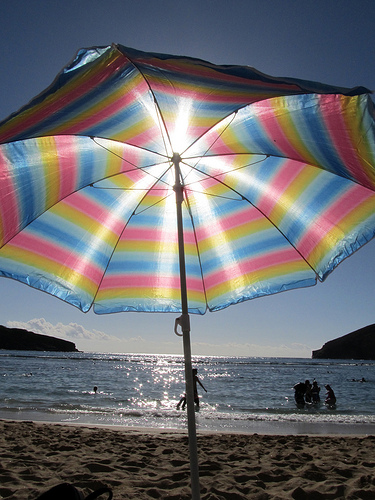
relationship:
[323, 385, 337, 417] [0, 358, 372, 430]
people in water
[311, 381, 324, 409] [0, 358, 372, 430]
people in water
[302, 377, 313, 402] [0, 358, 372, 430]
people in water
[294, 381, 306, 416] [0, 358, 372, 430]
people in water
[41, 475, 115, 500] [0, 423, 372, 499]
bag in sand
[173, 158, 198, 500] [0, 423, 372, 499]
pole in sand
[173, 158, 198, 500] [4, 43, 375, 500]
pole from umbrella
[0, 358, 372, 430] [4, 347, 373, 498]
water in a bay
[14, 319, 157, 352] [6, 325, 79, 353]
clouds are over hill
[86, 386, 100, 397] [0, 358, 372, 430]
head in water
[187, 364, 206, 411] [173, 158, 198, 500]
man behind pole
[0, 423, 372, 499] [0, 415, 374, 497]
sand has track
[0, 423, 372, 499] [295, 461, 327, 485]
sand has track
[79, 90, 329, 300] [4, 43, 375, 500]
sun through umbrella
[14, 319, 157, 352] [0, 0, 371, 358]
clouds are in sky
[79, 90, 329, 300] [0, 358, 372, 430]
sun reflecting on water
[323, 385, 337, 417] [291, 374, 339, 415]
people in group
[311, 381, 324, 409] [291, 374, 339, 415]
people in group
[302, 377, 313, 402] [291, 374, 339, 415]
people in group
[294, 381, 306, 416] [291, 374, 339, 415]
people in group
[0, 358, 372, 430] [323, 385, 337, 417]
water has people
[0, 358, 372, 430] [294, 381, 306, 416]
water has people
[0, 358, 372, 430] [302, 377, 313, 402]
water has people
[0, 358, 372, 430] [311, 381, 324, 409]
water has people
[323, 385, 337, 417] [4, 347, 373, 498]
people in bay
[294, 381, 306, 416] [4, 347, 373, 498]
people in bay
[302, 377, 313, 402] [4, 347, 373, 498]
people in bay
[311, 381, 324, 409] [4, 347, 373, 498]
people in bay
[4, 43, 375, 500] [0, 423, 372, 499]
umbrella in sand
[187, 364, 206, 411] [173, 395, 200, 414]
man walking h dog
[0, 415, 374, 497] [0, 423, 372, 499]
track on sand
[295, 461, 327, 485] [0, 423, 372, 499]
track on sand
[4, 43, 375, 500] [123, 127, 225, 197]
umbrella has rainbow stripes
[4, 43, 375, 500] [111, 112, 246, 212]
umbrella has rainbow stripes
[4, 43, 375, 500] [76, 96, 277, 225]
umbrella has rainbow stripes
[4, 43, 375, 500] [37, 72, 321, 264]
umbrella has rainbow stripes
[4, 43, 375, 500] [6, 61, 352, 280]
umbrella has rainbow stripes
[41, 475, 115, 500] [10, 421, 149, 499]
bag on left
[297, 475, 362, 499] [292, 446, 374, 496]
rocky cliff on right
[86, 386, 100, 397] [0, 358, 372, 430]
head poking out of water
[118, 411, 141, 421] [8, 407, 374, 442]
rock on shore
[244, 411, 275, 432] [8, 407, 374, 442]
rock on shore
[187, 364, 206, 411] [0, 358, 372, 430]
man bobbing water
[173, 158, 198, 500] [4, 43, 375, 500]
pole at umbrella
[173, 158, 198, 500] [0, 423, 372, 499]
pole on sand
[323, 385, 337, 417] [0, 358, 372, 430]
people swimming in water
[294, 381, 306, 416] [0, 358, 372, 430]
people swimming in water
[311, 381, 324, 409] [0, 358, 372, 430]
people swimming in water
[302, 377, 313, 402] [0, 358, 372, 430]
people swimming in water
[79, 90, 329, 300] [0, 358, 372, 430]
sun glinting water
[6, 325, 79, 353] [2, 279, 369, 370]
hill in distance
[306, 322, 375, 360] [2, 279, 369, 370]
rocky oucropping in distance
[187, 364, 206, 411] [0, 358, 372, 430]
man on water